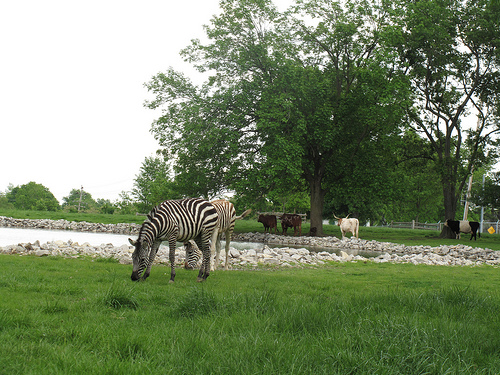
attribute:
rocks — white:
[239, 243, 324, 268]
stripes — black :
[168, 203, 197, 240]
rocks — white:
[342, 252, 348, 266]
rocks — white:
[294, 245, 309, 255]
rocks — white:
[243, 250, 253, 257]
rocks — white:
[377, 252, 385, 263]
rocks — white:
[292, 254, 302, 259]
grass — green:
[1, 263, 496, 373]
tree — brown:
[140, 0, 431, 237]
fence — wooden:
[378, 214, 498, 231]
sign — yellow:
[486, 224, 495, 234]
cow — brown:
[278, 211, 306, 235]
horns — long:
[326, 203, 355, 218]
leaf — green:
[208, 136, 224, 147]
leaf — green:
[186, 146, 196, 153]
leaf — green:
[188, 102, 197, 112]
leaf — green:
[193, 161, 205, 175]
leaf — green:
[279, 89, 294, 108]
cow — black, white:
[331, 213, 360, 237]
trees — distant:
[6, 180, 60, 209]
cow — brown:
[261, 213, 278, 237]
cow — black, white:
[441, 213, 484, 244]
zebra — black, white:
[127, 149, 238, 282]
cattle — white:
[326, 209, 363, 241]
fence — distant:
[384, 217, 443, 232]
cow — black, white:
[439, 215, 467, 242]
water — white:
[0, 227, 265, 249]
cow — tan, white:
[332, 210, 367, 240]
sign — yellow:
[486, 224, 496, 236]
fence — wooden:
[381, 217, 448, 233]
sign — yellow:
[481, 209, 496, 224]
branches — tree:
[410, 73, 481, 195]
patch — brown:
[330, 216, 346, 230]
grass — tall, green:
[101, 281, 496, 372]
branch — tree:
[457, 118, 490, 196]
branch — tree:
[442, 3, 494, 129]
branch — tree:
[350, 149, 430, 192]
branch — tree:
[416, 2, 461, 142]